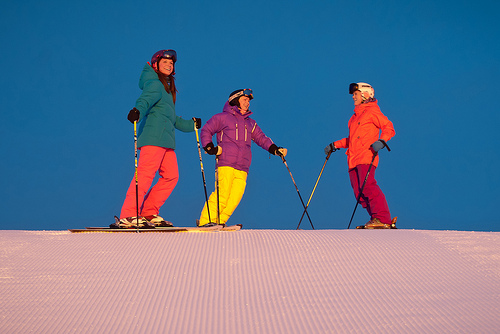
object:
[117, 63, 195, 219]
green and orange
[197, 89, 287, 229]
woman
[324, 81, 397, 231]
woman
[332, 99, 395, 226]
orange and purple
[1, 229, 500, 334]
hill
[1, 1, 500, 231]
sky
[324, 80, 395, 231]
girl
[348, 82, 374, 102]
helmet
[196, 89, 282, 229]
girl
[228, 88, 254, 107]
helmet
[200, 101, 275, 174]
coat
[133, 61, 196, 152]
coat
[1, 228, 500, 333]
tracks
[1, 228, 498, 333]
snow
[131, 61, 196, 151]
jacket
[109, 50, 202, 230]
teenage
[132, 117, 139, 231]
ski pole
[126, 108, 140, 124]
glove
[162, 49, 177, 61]
googles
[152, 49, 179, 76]
head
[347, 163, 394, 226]
pants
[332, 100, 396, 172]
coat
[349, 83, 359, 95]
googles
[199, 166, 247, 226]
pants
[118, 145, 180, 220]
pants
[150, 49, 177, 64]
helmet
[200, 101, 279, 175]
jacket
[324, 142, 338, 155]
gloves